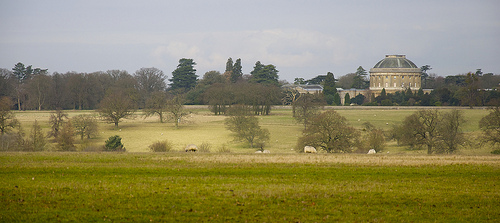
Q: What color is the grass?
A: Green.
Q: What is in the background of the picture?
A: Buildings.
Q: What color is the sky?
A: Blue.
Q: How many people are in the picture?
A: 0.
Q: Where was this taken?
A: Field.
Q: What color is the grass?
A: Green.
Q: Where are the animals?
A: In the field.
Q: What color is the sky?
A: Blue.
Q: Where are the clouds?
A: In the sky.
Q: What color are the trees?
A: Green.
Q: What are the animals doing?
A: Grazing.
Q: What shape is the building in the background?
A: Cylinder.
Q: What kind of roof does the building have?
A: Dome.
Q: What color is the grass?
A: Green.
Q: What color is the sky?
A: Blue.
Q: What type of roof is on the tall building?
A: Dome.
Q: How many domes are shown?
A: One.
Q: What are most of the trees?
A: Sparse.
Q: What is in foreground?
A: Field.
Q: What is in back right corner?
A: Large building.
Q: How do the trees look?
A: Healthy.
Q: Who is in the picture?
A: Noone.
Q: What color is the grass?
A: Green.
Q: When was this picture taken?
A: Morning.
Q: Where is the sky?
A: Above everything.